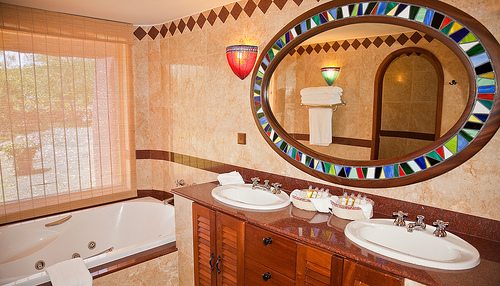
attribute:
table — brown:
[173, 180, 496, 284]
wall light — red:
[225, 42, 259, 80]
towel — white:
[43, 256, 92, 284]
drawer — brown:
[242, 228, 289, 260]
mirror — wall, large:
[248, 0, 498, 187]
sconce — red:
[219, 36, 275, 83]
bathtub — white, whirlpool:
[2, 195, 175, 284]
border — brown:
[135, 148, 499, 238]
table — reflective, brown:
[272, 213, 432, 280]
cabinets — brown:
[167, 190, 357, 283]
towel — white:
[26, 241, 97, 280]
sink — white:
[323, 182, 467, 284]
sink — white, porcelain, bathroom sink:
[209, 175, 293, 210]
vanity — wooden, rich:
[169, 180, 499, 283]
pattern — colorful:
[249, 0, 497, 152]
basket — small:
[284, 174, 324, 218]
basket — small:
[330, 177, 377, 220]